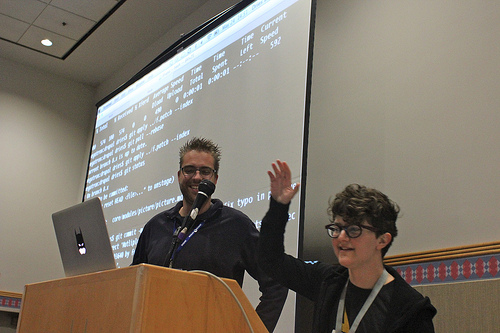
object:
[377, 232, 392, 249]
left ear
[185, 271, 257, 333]
wire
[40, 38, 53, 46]
light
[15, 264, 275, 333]
podium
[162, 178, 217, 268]
microphone podium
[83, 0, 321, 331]
display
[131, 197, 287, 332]
shirt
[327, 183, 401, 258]
hair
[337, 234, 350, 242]
nose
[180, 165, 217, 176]
glasses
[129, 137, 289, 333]
man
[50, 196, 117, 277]
laptop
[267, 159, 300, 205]
hand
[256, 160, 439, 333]
boy